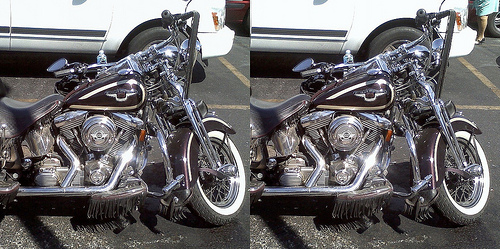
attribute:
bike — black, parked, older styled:
[10, 17, 243, 236]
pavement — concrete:
[6, 32, 250, 248]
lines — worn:
[205, 55, 251, 116]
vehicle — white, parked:
[251, 0, 478, 81]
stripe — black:
[252, 25, 349, 46]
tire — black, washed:
[371, 30, 433, 74]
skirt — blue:
[475, 0, 497, 15]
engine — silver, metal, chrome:
[51, 114, 147, 197]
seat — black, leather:
[1, 94, 62, 132]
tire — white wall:
[189, 127, 246, 223]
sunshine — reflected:
[122, 147, 138, 164]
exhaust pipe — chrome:
[23, 156, 138, 208]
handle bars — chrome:
[50, 14, 190, 74]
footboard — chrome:
[98, 176, 147, 202]